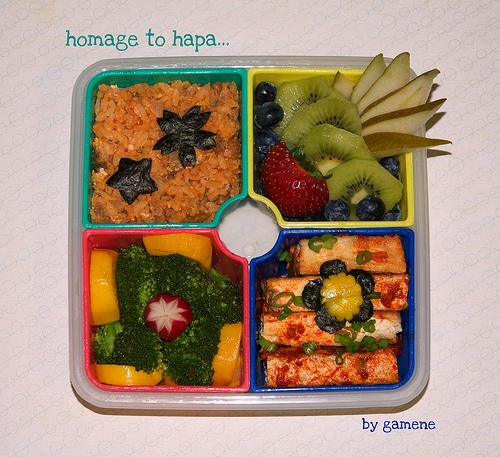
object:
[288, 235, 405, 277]
burritos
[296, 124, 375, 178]
kiwi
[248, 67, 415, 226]
container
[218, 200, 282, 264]
sauce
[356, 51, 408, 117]
pears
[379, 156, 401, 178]
blueberry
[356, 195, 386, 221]
blueberry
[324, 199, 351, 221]
blueberry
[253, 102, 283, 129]
blueberry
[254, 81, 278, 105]
blueberry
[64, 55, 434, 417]
container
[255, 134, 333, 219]
strawberry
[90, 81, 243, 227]
rice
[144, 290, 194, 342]
radish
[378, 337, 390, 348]
onions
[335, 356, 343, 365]
onions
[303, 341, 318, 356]
onions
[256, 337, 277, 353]
onions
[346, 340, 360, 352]
onions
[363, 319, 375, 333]
onions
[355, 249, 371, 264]
onions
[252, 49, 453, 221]
fruit